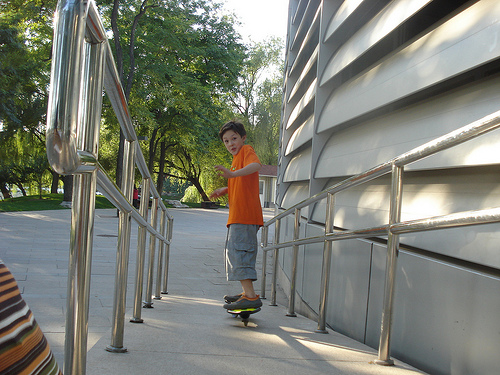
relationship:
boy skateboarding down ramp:
[205, 103, 265, 328] [145, 315, 190, 370]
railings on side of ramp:
[38, 15, 175, 372] [91, 294, 426, 374]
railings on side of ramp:
[261, 109, 498, 364] [91, 294, 426, 374]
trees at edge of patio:
[5, 0, 232, 187] [0, 207, 290, 369]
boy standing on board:
[205, 103, 265, 328] [226, 308, 261, 324]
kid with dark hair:
[209, 119, 266, 314] [217, 119, 247, 140]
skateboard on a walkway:
[224, 291, 264, 328] [84, 296, 426, 374]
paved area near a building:
[30, 267, 407, 374] [269, 0, 499, 373]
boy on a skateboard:
[205, 103, 265, 328] [223, 297, 262, 327]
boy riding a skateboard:
[205, 103, 265, 328] [226, 304, 260, 327]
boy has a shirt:
[205, 103, 265, 328] [224, 145, 266, 225]